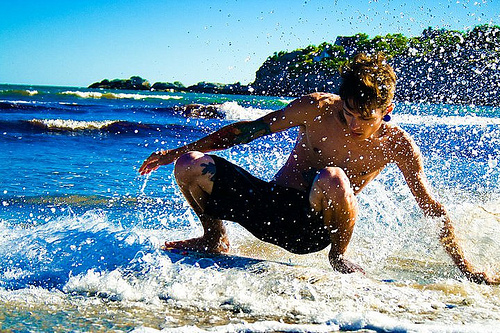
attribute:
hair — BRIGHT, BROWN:
[344, 44, 398, 111]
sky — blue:
[122, 20, 217, 75]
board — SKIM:
[135, 235, 498, 304]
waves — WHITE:
[137, 90, 499, 198]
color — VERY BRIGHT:
[53, 131, 81, 148]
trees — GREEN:
[412, 33, 472, 109]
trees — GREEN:
[257, 45, 443, 96]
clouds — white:
[109, 27, 249, 82]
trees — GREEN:
[251, 22, 498, 102]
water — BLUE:
[7, 129, 137, 194]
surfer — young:
[135, 48, 498, 289]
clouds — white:
[164, 31, 211, 63]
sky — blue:
[19, 5, 250, 74]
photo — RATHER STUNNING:
[28, 26, 442, 284]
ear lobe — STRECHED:
[384, 112, 391, 122]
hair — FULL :
[342, 48, 397, 109]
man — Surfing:
[137, 48, 498, 288]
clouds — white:
[225, 52, 255, 79]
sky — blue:
[20, 20, 124, 57]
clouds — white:
[39, 25, 260, 85]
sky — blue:
[2, 2, 496, 84]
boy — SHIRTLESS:
[132, 56, 498, 291]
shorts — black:
[203, 147, 335, 262]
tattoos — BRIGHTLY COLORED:
[162, 113, 272, 153]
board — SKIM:
[133, 221, 478, 316]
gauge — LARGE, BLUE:
[381, 114, 391, 121]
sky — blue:
[17, 3, 495, 110]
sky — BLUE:
[79, 30, 107, 48]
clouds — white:
[72, 0, 256, 55]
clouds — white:
[233, 59, 264, 69]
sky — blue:
[74, 21, 246, 65]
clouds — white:
[203, 39, 249, 52]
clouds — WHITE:
[160, 12, 260, 72]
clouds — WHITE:
[37, 32, 77, 58]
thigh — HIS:
[184, 149, 267, 201]